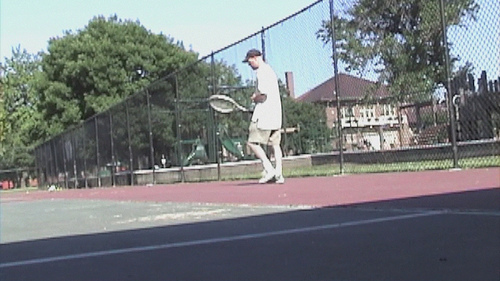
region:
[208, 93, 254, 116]
a white tennis racket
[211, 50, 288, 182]
a man holding a tennis racket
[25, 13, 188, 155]
a full green tree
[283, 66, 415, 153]
a very large house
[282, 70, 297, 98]
a tall red brick chimney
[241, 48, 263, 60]
a dark cap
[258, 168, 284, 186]
a pair of mens shoes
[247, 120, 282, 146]
a pair of shorts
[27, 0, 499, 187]
a tall and long chain link fence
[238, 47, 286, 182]
a man wearing a light outfit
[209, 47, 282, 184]
tennis player approaching the court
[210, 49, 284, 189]
a man approaching the court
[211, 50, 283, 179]
a young man approaching the court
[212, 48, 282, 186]
a person approaching the court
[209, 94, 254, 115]
tennis racquet being held in right hand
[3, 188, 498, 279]
shadow covering part of the court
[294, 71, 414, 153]
a three car garage behind the fence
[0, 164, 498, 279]
green, red and white tennis court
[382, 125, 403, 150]
the right door of the garage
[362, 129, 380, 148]
the center door of a garage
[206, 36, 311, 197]
Tennis player on the court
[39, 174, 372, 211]
Red side lines of the tennis court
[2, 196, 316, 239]
Green tennis court floor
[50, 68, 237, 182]
Black chain link fence on the backside of the court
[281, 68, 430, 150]
House in the distance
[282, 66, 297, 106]
Chimmey attached to the house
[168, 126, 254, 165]
Playground behind the tennis court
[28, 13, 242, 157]
Very large tree to the left of the tennis court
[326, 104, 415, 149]
House is brick and tan in color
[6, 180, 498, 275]
Tennis court in the shade.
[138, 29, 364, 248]
a man playing tennis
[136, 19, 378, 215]
the fence is black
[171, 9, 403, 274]
the court is clay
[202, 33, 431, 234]
a house in the background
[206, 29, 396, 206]
the man has a black hat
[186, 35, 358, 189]
the racket is white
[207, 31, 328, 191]
the shoes are white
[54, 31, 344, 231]
the leaves are green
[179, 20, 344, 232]
the man wears shorts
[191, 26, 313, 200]
the sport is tennis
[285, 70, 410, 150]
a house with a brown roof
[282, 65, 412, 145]
a house with a chimney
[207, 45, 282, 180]
man on a tennis court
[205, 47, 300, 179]
man holding a tennis racket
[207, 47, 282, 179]
man wearing a black cap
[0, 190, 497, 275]
area in the shade on the tennis court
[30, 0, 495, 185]
fence along the tennis court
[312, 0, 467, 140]
tree to the right of tennis player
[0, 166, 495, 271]
the tennis court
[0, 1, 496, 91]
clear sky over the tennis court